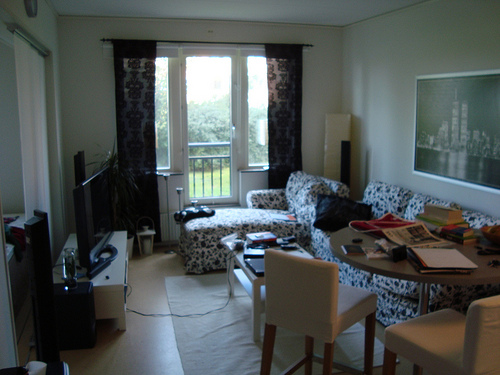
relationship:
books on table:
[444, 223, 473, 237] [328, 219, 498, 374]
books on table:
[439, 232, 476, 248] [328, 219, 498, 374]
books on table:
[418, 197, 466, 223] [328, 219, 498, 374]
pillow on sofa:
[295, 199, 401, 259] [256, 157, 492, 352]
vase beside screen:
[63, 245, 75, 277] [76, 165, 116, 266]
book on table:
[245, 227, 277, 244] [223, 235, 319, 342]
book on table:
[244, 240, 266, 257] [223, 235, 319, 342]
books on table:
[415, 206, 495, 261] [233, 198, 499, 373]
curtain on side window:
[13, 36, 52, 268] [0, 20, 28, 260]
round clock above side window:
[25, 0, 37, 17] [0, 20, 60, 260]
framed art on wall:
[411, 66, 498, 199] [340, 0, 499, 212]